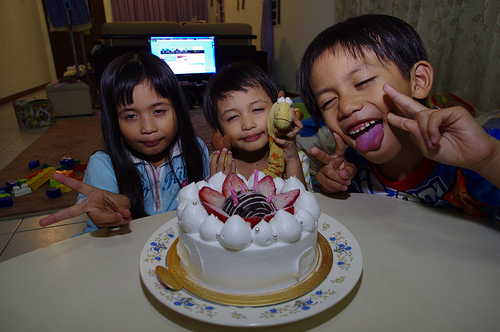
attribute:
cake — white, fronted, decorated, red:
[159, 170, 313, 264]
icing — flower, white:
[217, 170, 322, 221]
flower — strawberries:
[206, 187, 301, 226]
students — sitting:
[82, 28, 471, 148]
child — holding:
[256, 92, 311, 155]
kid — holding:
[245, 75, 316, 158]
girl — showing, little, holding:
[100, 58, 183, 201]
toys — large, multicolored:
[17, 137, 78, 213]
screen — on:
[160, 37, 224, 91]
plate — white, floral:
[151, 294, 250, 326]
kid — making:
[366, 36, 472, 159]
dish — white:
[135, 213, 207, 327]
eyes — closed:
[331, 66, 387, 117]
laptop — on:
[141, 24, 260, 96]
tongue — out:
[338, 111, 375, 160]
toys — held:
[242, 97, 307, 190]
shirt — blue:
[71, 150, 215, 234]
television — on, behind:
[136, 31, 233, 84]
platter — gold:
[231, 284, 324, 311]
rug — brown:
[46, 123, 107, 169]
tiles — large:
[11, 218, 73, 250]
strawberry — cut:
[227, 188, 277, 240]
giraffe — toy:
[250, 95, 303, 171]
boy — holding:
[322, 39, 465, 193]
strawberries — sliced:
[192, 160, 274, 232]